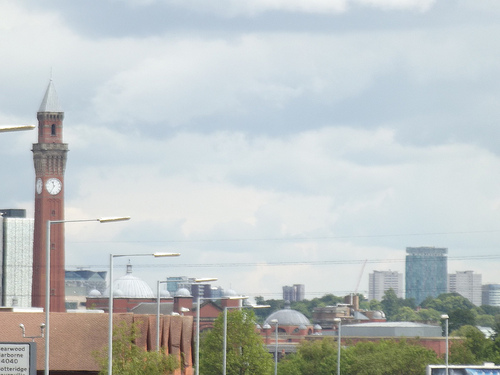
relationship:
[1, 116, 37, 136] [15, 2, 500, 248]
bird in sky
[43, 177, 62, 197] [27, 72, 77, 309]
clock on tower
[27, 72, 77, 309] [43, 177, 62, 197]
tower with clock